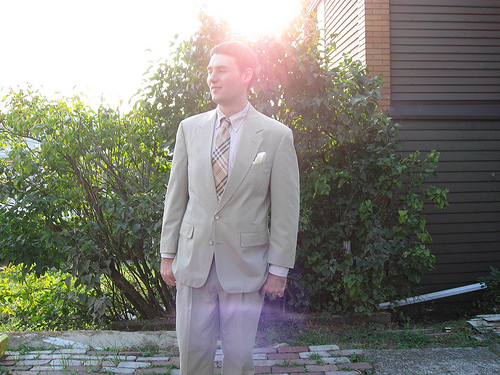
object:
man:
[157, 38, 306, 374]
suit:
[157, 101, 305, 374]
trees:
[0, 5, 460, 320]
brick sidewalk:
[304, 363, 338, 374]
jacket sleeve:
[265, 258, 295, 277]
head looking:
[203, 37, 259, 105]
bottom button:
[207, 240, 217, 249]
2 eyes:
[201, 65, 229, 77]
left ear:
[241, 66, 258, 87]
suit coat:
[157, 102, 305, 296]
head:
[202, 38, 262, 105]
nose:
[209, 72, 220, 82]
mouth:
[207, 84, 227, 94]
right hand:
[158, 258, 181, 289]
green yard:
[1, 82, 163, 329]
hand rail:
[307, 281, 500, 316]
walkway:
[3, 333, 374, 374]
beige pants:
[171, 262, 270, 374]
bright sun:
[206, 1, 314, 44]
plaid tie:
[209, 116, 233, 199]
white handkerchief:
[253, 148, 269, 167]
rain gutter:
[268, 0, 324, 27]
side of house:
[305, 2, 388, 120]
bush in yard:
[0, 4, 466, 375]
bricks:
[268, 351, 302, 356]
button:
[212, 211, 223, 222]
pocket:
[237, 222, 270, 249]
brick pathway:
[305, 344, 342, 351]